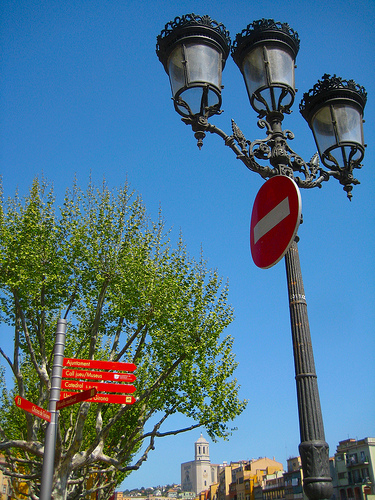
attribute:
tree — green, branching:
[3, 175, 240, 499]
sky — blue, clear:
[0, 0, 375, 458]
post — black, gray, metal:
[254, 147, 351, 499]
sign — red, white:
[241, 171, 314, 280]